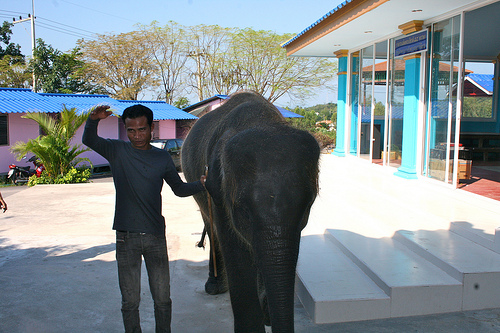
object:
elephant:
[178, 88, 318, 326]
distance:
[3, 0, 340, 108]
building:
[2, 83, 202, 183]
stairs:
[298, 215, 497, 326]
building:
[259, 0, 496, 333]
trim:
[415, 51, 425, 180]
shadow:
[2, 231, 497, 330]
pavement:
[2, 183, 493, 330]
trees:
[206, 33, 283, 101]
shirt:
[105, 140, 175, 228]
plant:
[6, 98, 96, 186]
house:
[2, 82, 188, 167]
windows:
[442, 10, 496, 200]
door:
[451, 0, 498, 200]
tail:
[195, 224, 208, 249]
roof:
[0, 83, 203, 123]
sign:
[389, 23, 434, 61]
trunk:
[249, 216, 303, 331]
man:
[79, 94, 217, 330]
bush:
[12, 106, 91, 188]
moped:
[5, 155, 44, 186]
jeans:
[114, 231, 173, 331]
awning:
[0, 86, 191, 120]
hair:
[120, 104, 154, 125]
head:
[117, 104, 152, 147]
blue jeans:
[114, 229, 173, 330]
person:
[79, 100, 201, 326]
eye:
[238, 197, 254, 207]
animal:
[176, 86, 321, 330]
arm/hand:
[81, 102, 115, 161]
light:
[59, 216, 95, 241]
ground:
[26, 186, 107, 310]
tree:
[12, 106, 93, 186]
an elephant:
[176, 89, 320, 331]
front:
[342, 10, 478, 196]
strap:
[196, 135, 224, 281]